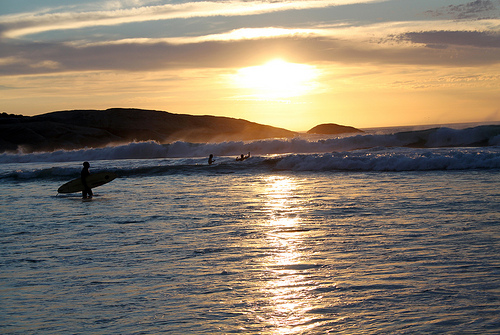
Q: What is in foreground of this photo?
A: Ocean.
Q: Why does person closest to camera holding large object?
A: They're surfing.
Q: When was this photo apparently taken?
A: Sundown.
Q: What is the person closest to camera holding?
A: Surfboard.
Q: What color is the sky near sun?
A: Yellowish-orange.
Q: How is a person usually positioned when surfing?
A: Upright.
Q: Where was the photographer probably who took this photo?
A: On shore.